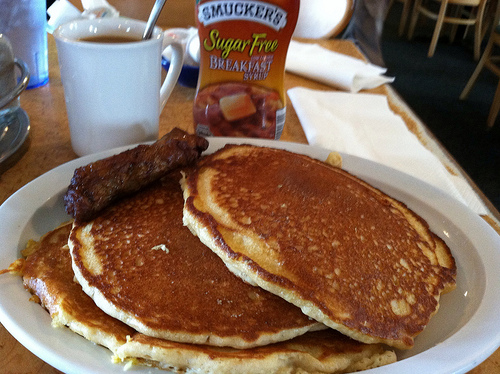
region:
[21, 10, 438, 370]
A plate of food.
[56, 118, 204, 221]
A piece of sausage link.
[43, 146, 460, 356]
Three pancakes.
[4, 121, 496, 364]
A round white plate.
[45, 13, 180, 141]
A white coffee cup.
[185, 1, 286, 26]
The name brand SMUCKER'S.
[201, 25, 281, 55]
The words Sugar Free in yellow letters.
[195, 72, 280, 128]
Picture of pancakes on syrup bottle.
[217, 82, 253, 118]
A pat of butter on picture of pancakes.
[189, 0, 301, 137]
A container of syrup for pancakes.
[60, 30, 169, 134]
this is a cup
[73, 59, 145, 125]
the cup is white in color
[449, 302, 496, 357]
the plate is white in color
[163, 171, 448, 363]
these are a few pancakes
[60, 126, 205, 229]
this is a sausage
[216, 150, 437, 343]
the pancake is big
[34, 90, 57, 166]
this is a table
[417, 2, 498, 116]
these are some chairs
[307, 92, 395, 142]
white handkerchief on the table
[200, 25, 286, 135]
this is a plastic container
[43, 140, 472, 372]
Pancakes on a white plate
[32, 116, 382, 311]
Sausage right by pancakes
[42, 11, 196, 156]
White cup with silver spoon inside the cup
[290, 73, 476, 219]
White napkins are by plate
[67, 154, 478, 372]
Pancakes are crispy in texture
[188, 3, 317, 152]
Bottle of breakfast syrup is on the table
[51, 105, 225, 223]
The sausage is crispy in texture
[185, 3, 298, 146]
Pancake syrup bottle is orange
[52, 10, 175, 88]
Coffee is inside white cup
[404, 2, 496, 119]
Wooden chairs are in the background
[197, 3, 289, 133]
A sugar free pancake syrup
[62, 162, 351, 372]
A sausage and pancakes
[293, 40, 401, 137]
two napkins on the table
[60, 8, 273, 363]
A cup of coffee to go with the meal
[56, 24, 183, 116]
coffee in a white cup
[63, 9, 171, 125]
A spoon in the coffee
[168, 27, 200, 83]
Creamers for the coffee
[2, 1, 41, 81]
Some ice water in a cup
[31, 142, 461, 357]
Pancakes and a sausage on a white plate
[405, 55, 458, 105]
carpet floor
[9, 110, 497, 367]
pancakes on a plate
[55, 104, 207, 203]
sausage on a plate with pancakes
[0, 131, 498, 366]
pancakes and susage on a white ceramic plate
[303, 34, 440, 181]
white napkins on the table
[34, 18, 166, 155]
white ceramic coffee mug with coffee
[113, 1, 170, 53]
spoon in coffee mug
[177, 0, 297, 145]
sugar free breakfast syrup for pancakes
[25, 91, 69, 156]
table surface is light brown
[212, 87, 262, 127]
square piece of butter on front of syrup container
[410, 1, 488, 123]
legs of pale tan colored chairs